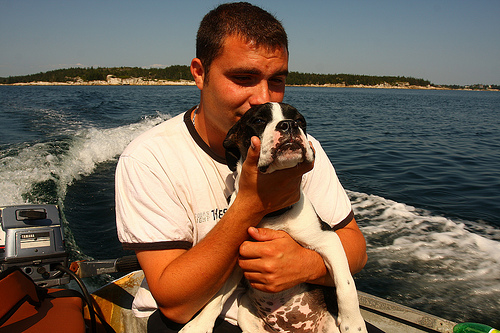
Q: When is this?
A: Daytime.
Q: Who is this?
A: A man.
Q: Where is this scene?
A: On a boat.